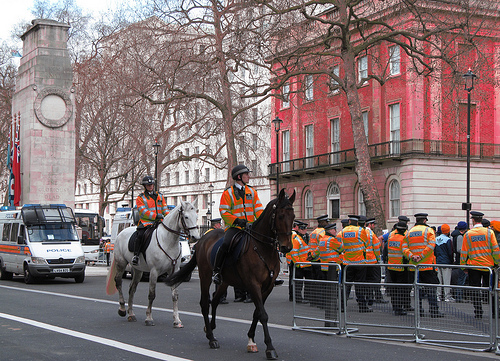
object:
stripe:
[0, 247, 33, 252]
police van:
[1, 203, 87, 283]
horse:
[166, 187, 295, 360]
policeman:
[218, 165, 287, 286]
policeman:
[131, 176, 171, 266]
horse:
[106, 194, 202, 328]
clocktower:
[11, 18, 75, 215]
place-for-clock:
[32, 86, 74, 127]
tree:
[332, 1, 386, 236]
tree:
[208, 1, 247, 191]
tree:
[142, 1, 170, 218]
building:
[268, 1, 500, 233]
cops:
[459, 210, 500, 319]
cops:
[403, 211, 443, 318]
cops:
[318, 223, 344, 328]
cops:
[386, 222, 408, 316]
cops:
[295, 219, 308, 245]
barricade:
[417, 263, 495, 351]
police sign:
[45, 247, 71, 254]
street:
[1, 282, 93, 361]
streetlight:
[459, 68, 477, 228]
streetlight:
[272, 115, 282, 197]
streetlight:
[152, 140, 160, 192]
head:
[261, 187, 296, 254]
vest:
[218, 185, 263, 230]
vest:
[136, 191, 169, 227]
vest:
[460, 227, 500, 270]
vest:
[401, 225, 439, 271]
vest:
[387, 232, 406, 272]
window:
[388, 104, 401, 156]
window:
[329, 121, 341, 166]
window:
[306, 124, 314, 169]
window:
[283, 131, 289, 170]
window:
[389, 45, 401, 76]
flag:
[12, 112, 21, 206]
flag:
[5, 115, 12, 207]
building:
[75, 15, 271, 236]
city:
[1, 0, 498, 361]